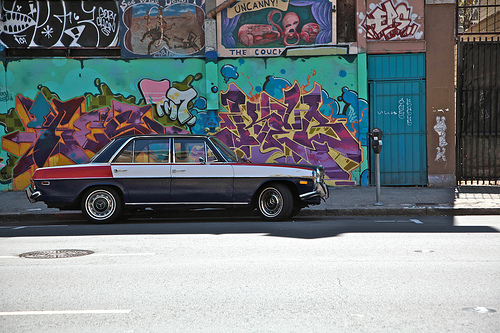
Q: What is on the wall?
A: Colorful graffiti.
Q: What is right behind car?
A: Side walk mostly in shadow.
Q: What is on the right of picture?
A: Black metal gated entrance.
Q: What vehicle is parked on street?
A: Car.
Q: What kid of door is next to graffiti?
A: Tall light blue door.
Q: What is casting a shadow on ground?
A: A building.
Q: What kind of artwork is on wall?
A: Graffiti.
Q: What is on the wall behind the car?
A: Graffiti.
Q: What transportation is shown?
A: Car.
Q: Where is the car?
A: Parked on side of road.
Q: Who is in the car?
A: No body.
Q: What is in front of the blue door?
A: Parking meter.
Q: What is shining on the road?
A: Sun.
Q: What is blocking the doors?
A: Gates.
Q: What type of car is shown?
A: Sedan.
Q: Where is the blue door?
A: In wall on right.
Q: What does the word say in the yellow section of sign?
A: Uncanny.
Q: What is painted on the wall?
A: Graffiti.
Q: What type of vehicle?
A: Car.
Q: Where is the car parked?
A: The street.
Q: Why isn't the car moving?
A: It is parked.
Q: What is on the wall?
A: Graffiti.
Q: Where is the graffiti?
A: On the wall.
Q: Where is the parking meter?
A: In front of the car.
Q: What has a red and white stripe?
A: Car.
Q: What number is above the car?
A: 7.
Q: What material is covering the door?
A: Metal.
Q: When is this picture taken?
A: Daytime.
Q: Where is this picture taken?
A: Road.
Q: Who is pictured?
A: No one.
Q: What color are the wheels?
A: Silver and black.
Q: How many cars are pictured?
A: One.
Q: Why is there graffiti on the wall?
A: Art.